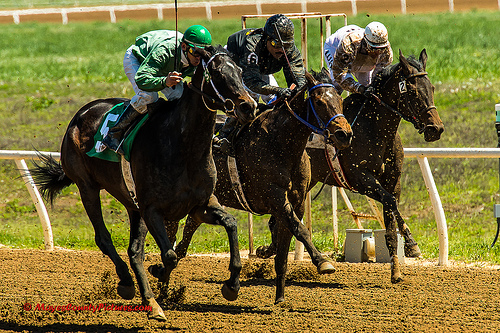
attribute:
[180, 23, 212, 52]
helmet — green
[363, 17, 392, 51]
helmet — white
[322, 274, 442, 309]
ground — white, metal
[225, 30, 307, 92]
jacket — black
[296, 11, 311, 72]
post — long, white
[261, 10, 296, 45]
helmet — black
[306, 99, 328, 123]
horse bridle — blue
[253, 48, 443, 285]
horse — large, brown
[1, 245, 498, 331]
track — dirt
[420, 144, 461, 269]
post — metal, large, white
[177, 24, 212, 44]
helmet — green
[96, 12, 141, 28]
post — white, long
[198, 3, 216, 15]
post — long, white, metallic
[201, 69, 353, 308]
horse — large, brown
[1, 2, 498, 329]
track — dirt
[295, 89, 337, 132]
horse bridle — brown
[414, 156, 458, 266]
post — long, white, metal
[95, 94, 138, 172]
boots — riding boots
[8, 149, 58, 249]
post — white, large, metal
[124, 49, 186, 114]
pants — jockey, long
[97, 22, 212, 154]
man — wearing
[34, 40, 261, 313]
horse — 3, brown, large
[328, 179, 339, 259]
metal post — long, white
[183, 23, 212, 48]
helmet — green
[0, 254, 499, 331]
dirt — brown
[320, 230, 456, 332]
ground — large, white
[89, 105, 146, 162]
saddle — green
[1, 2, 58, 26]
post — large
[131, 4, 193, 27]
post — metal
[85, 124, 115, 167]
boots — long, black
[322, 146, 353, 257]
post — long, white